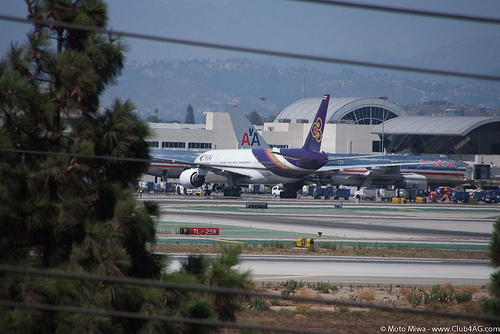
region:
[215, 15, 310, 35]
hazy sky in the distance.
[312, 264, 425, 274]
runway made of concrete.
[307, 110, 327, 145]
logo on tail of plane.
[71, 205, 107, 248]
pine needles on tree.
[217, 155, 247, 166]
windows on side of plane.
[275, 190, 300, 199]
wheels of the airplane.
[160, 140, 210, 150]
windows on the building.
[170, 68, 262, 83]
mountain behind the airport.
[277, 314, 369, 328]
grass near the runway.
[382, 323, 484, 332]
writing in corner of photo.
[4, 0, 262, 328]
the green pine tree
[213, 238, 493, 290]
the runway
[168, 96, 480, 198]
the airplanes at the airport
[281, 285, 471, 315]
the plants near the runway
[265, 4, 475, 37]
the sky is clear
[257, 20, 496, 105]
the mountains behind the airport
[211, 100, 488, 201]
the american airlines airplane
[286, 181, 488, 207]
the luggage on the runway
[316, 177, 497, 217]
the luggage is being loaded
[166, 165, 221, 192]
the engine of the airplane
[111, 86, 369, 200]
A parked Airplane at the airport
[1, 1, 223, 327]
A green Pine tree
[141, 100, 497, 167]
An Airport Terminal Building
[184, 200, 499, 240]
A Section of Airport Runway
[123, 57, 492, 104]
Barely Visible mountains and hills in the background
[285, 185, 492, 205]
Various Vehicles around the Airport Terminal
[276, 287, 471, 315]
A Dry patch of Desert Ground near the Runway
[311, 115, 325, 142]
A Design on an Airplane Tail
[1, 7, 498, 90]
Thick Gauge Fence Wire around the Airport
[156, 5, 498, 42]
Grey Sky above the hills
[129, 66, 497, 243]
the plane has wings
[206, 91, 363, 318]
the plane has wings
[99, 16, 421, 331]
the plane has wings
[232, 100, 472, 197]
american airlines plane parked at the gate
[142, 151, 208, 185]
midsection of a second american airlines plane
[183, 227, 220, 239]
red sign identifying the runways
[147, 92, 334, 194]
plane from unknown airline awaiting a turn at the gate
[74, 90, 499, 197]
airport passenger building of unknown city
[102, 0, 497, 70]
hazy overcast sky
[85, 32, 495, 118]
rugged looking hills behind airport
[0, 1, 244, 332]
tall evergreen tree growing off the runway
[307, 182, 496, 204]
support personnel and vehicles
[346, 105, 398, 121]
huge curved window of passenger terminal